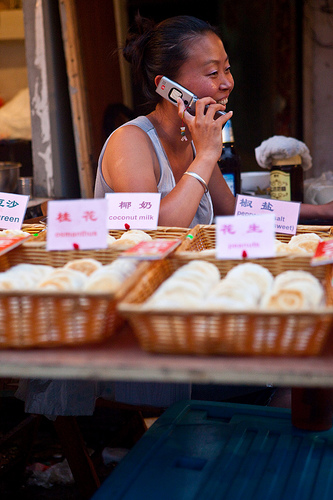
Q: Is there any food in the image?
A: Yes, there is food.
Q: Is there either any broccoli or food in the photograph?
A: Yes, there is food.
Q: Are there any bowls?
A: No, there are no bowls.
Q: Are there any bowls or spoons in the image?
A: No, there are no bowls or spoons.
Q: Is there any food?
A: Yes, there is food.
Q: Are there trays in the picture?
A: No, there are no trays.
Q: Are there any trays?
A: No, there are no trays.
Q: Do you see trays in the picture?
A: No, there are no trays.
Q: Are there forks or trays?
A: No, there are no trays or forks.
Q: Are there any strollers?
A: No, there are no strollers.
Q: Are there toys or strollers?
A: No, there are no strollers or toys.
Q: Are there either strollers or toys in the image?
A: No, there are no strollers or toys.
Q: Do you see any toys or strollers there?
A: No, there are no strollers or toys.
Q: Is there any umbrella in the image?
A: No, there are no umbrellas.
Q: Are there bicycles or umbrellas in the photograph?
A: No, there are no umbrellas or bicycles.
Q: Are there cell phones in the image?
A: Yes, there is a cell phone.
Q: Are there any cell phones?
A: Yes, there is a cell phone.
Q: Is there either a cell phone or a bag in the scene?
A: Yes, there is a cell phone.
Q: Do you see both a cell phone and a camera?
A: No, there is a cell phone but no cameras.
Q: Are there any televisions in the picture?
A: No, there are no televisions.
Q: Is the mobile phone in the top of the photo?
A: Yes, the mobile phone is in the top of the image.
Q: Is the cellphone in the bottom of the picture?
A: No, the cellphone is in the top of the image.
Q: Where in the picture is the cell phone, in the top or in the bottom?
A: The cell phone is in the top of the image.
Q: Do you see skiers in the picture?
A: No, there are no skiers.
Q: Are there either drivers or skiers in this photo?
A: No, there are no skiers or drivers.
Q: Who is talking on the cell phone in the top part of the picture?
A: The lady is talking on the cellphone.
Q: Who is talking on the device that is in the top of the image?
A: The lady is talking on the cellphone.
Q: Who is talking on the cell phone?
A: The lady is talking on the cellphone.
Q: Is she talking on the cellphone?
A: Yes, the lady is talking on the cellphone.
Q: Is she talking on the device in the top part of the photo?
A: Yes, the lady is talking on the cellphone.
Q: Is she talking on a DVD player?
A: No, the lady is talking on the cellphone.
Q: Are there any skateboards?
A: No, there are no skateboards.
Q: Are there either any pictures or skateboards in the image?
A: No, there are no skateboards or pictures.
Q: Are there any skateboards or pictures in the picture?
A: No, there are no skateboards or pictures.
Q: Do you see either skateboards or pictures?
A: No, there are no skateboards or pictures.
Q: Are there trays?
A: No, there are no trays.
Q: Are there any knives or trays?
A: No, there are no trays or knives.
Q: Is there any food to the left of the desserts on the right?
A: Yes, there is food to the left of the desserts.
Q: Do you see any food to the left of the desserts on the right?
A: Yes, there is food to the left of the desserts.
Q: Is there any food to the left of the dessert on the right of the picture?
A: Yes, there is food to the left of the desserts.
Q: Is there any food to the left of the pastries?
A: Yes, there is food to the left of the pastries.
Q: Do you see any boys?
A: No, there are no boys.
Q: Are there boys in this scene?
A: No, there are no boys.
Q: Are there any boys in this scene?
A: No, there are no boys.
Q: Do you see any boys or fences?
A: No, there are no boys or fences.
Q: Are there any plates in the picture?
A: No, there are no plates.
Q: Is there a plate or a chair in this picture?
A: No, there are no plates or chairs.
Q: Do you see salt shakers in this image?
A: No, there are no salt shakers.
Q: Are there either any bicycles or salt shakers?
A: No, there are no salt shakers or bicycles.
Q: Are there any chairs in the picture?
A: No, there are no chairs.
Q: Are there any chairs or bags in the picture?
A: No, there are no chairs or bags.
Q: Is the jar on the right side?
A: Yes, the jar is on the right of the image.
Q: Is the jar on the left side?
A: No, the jar is on the right of the image.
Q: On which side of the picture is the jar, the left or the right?
A: The jar is on the right of the image.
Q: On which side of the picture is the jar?
A: The jar is on the right of the image.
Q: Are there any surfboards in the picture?
A: No, there are no surfboards.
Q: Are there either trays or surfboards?
A: No, there are no surfboards or trays.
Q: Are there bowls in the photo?
A: No, there are no bowls.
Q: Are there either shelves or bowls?
A: No, there are no bowls or shelves.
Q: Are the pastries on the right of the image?
A: Yes, the pastries are on the right of the image.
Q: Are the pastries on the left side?
A: No, the pastries are on the right of the image.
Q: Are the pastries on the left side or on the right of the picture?
A: The pastries are on the right of the image.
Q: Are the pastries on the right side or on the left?
A: The pastries are on the right of the image.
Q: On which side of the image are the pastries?
A: The pastries are on the right of the image.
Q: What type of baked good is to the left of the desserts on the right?
A: The food is pastries.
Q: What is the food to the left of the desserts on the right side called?
A: The food is pastries.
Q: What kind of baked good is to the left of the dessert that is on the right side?
A: The food is pastries.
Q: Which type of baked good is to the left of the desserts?
A: The food is pastries.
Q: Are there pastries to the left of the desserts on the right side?
A: Yes, there are pastries to the left of the desserts.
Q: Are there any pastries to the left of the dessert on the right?
A: Yes, there are pastries to the left of the desserts.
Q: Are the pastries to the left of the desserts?
A: Yes, the pastries are to the left of the desserts.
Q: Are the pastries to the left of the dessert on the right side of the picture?
A: Yes, the pastries are to the left of the desserts.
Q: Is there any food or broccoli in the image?
A: Yes, there is food.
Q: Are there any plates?
A: No, there are no plates.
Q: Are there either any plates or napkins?
A: No, there are no plates or napkins.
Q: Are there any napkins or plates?
A: No, there are no plates or napkins.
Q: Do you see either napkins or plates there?
A: No, there are no plates or napkins.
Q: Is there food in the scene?
A: Yes, there is food.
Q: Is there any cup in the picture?
A: No, there are no cups.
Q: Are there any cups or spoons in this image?
A: No, there are no cups or spoons.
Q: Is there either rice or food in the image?
A: Yes, there is food.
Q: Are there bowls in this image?
A: No, there are no bowls.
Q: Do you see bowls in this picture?
A: No, there are no bowls.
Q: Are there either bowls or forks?
A: No, there are no bowls or forks.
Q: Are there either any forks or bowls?
A: No, there are no bowls or forks.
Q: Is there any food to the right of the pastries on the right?
A: Yes, there is food to the right of the pastries.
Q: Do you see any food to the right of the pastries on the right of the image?
A: Yes, there is food to the right of the pastries.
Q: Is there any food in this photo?
A: Yes, there is food.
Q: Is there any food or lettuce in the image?
A: Yes, there is food.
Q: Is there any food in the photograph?
A: Yes, there is food.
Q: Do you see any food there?
A: Yes, there is food.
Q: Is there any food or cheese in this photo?
A: Yes, there is food.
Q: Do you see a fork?
A: No, there are no forks.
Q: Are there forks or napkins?
A: No, there are no forks or napkins.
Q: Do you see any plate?
A: No, there are no plates.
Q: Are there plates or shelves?
A: No, there are no plates or shelves.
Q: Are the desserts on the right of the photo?
A: Yes, the desserts are on the right of the image.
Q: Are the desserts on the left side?
A: No, the desserts are on the right of the image.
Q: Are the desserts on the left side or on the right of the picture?
A: The desserts are on the right of the image.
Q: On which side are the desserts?
A: The desserts are on the right of the image.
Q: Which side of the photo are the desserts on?
A: The desserts are on the right of the image.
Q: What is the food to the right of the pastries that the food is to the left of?
A: The food is desserts.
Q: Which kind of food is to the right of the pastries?
A: The food is desserts.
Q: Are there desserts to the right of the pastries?
A: Yes, there are desserts to the right of the pastries.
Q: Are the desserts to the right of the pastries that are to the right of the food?
A: Yes, the desserts are to the right of the pastries.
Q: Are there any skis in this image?
A: No, there are no skis.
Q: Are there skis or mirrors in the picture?
A: No, there are no skis or mirrors.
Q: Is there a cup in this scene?
A: No, there are no cups.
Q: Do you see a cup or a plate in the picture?
A: No, there are no cups or plates.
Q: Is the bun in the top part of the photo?
A: Yes, the bun is in the top of the image.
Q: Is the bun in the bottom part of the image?
A: No, the bun is in the top of the image.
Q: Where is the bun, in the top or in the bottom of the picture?
A: The bun is in the top of the image.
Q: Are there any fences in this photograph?
A: No, there are no fences.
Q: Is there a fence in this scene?
A: No, there are no fences.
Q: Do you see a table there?
A: Yes, there is a table.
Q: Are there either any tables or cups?
A: Yes, there is a table.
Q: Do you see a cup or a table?
A: Yes, there is a table.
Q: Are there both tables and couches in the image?
A: No, there is a table but no couches.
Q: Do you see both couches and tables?
A: No, there is a table but no couches.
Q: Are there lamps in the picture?
A: No, there are no lamps.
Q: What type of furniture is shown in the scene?
A: The furniture is a table.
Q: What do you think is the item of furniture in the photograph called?
A: The piece of furniture is a table.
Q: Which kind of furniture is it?
A: The piece of furniture is a table.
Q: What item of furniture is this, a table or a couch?
A: That is a table.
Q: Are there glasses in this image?
A: No, there are no glasses.